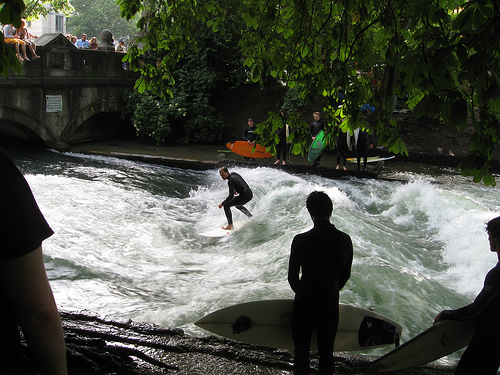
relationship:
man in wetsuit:
[213, 165, 256, 230] [227, 172, 253, 223]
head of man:
[219, 168, 230, 182] [213, 165, 256, 230]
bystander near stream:
[0, 135, 68, 374] [5, 150, 498, 339]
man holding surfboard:
[285, 190, 354, 373] [193, 297, 402, 352]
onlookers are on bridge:
[4, 18, 43, 63] [0, 32, 145, 149]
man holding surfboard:
[244, 116, 259, 163] [224, 138, 276, 161]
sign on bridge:
[44, 93, 65, 113] [0, 32, 145, 149]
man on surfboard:
[213, 165, 256, 230] [202, 217, 250, 239]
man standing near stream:
[285, 190, 354, 373] [5, 150, 498, 339]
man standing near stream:
[244, 116, 259, 163] [5, 150, 498, 339]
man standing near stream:
[310, 110, 323, 170] [5, 150, 498, 339]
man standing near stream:
[333, 115, 349, 171] [5, 150, 498, 339]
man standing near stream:
[352, 120, 372, 175] [5, 150, 498, 339]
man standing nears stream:
[433, 217, 498, 372] [5, 150, 498, 339]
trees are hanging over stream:
[116, 1, 499, 185] [5, 150, 498, 339]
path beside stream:
[68, 130, 499, 183] [5, 150, 498, 339]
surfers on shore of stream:
[226, 105, 373, 175] [5, 150, 498, 339]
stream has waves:
[5, 150, 498, 339] [211, 165, 500, 359]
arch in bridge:
[0, 117, 45, 149] [0, 32, 145, 149]